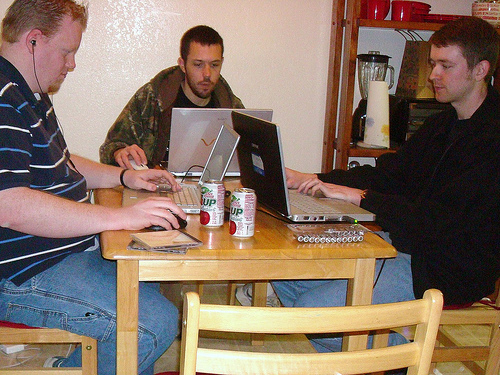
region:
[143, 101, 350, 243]
three laptops kept in the dining table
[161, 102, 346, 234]
all three laptops are kept open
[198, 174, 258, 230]
7 up tin kept in the table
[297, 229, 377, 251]
bunch of batteries kept in the table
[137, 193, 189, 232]
a person holding black color mouse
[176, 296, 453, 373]
wooden chair near the table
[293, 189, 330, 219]
keyboard in the laptop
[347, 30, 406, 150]
mixer grinder kept in the rack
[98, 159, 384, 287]
wooden dining table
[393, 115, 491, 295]
a person wearing black color shirt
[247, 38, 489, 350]
Man sitting at table on laptop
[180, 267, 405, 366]
Chair made out of wood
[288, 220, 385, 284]
Batteries sitting on table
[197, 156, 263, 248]
Sodas on the table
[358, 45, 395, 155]
Blender on the shelf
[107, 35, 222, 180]
Man wearing a coat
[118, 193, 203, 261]
Man touching a mouse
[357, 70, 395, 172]
Cup upside down on shelf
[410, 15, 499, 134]
Man has short hair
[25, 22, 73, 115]
Man wearing ear buds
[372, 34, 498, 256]
A man seated watching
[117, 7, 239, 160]
A man seated watching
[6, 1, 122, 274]
A man seated watching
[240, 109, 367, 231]
A black laptop on the table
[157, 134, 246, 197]
A black laptop on the table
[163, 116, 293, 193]
A black laptop on the table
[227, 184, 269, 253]
A enery drink cane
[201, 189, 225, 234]
A enery drink cane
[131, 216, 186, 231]
A hand on a black mouse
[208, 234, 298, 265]
A wooden brown table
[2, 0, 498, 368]
Three men sitting at a table using laptops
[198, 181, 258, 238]
Two beverage cans on the table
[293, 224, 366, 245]
Package of batteries on the table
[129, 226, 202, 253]
CD cases on the table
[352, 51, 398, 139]
Blender on the counter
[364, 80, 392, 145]
Roll of paper towels in front of blender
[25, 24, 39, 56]
Ear bud in man's ear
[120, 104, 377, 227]
Three laptop computers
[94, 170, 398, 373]
Wooden table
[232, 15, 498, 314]
Man using laptop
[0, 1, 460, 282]
three young men sitting at a table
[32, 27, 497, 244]
three young men using laptop computers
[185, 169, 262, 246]
two drink cans on a table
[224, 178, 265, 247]
a drink can on a table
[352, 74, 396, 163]
a roll of paper towels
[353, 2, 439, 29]
stacks of red dishes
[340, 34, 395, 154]
a drink blender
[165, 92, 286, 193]
three laptop computers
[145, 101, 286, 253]
three laptop computers on a table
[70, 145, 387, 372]
a wood table and chairs